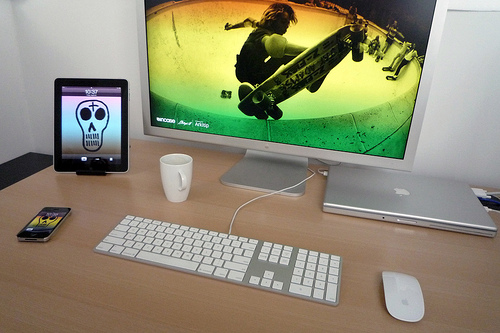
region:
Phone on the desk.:
[8, 201, 81, 254]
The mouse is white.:
[374, 248, 438, 330]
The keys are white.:
[93, 204, 350, 331]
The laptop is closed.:
[331, 166, 491, 244]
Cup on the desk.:
[154, 145, 204, 207]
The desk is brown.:
[33, 266, 209, 331]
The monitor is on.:
[124, 10, 433, 167]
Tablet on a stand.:
[45, 73, 135, 188]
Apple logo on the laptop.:
[381, 178, 428, 205]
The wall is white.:
[2, 3, 149, 71]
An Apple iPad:
[45, 70, 136, 193]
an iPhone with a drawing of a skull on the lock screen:
[15, 198, 71, 245]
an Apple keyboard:
[98, 198, 350, 310]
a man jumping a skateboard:
[148, 0, 414, 147]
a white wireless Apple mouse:
[375, 260, 432, 330]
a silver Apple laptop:
[318, 153, 497, 241]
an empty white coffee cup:
[150, 146, 197, 208]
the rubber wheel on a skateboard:
[247, 88, 272, 116]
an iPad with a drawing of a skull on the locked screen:
[45, 69, 135, 184]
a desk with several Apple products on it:
[2, 3, 490, 325]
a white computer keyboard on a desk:
[83, 207, 365, 317]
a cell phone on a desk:
[3, 174, 98, 261]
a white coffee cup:
[139, 138, 216, 216]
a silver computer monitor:
[123, 9, 452, 162]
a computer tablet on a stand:
[23, 38, 139, 188]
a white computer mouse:
[353, 263, 450, 332]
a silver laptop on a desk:
[297, 165, 496, 242]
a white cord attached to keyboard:
[218, 161, 326, 243]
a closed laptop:
[316, 172, 498, 237]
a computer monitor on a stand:
[120, 11, 462, 198]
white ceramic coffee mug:
[155, 145, 200, 202]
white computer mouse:
[382, 258, 429, 325]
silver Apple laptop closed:
[319, 153, 496, 240]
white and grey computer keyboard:
[90, 206, 355, 319]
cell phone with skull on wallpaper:
[16, 198, 71, 245]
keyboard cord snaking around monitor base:
[223, 167, 324, 242]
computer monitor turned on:
[135, 15, 429, 161]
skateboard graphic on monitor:
[218, 4, 363, 111]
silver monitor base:
[214, 141, 322, 208]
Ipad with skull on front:
[50, 68, 131, 183]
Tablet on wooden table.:
[55, 78, 133, 174]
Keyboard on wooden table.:
[91, 205, 345, 305]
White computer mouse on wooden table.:
[378, 267, 425, 320]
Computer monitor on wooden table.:
[131, 0, 456, 197]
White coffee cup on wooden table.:
[152, 152, 198, 205]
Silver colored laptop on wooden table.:
[320, 160, 498, 233]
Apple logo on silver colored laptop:
[386, 181, 414, 201]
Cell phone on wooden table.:
[12, 200, 72, 245]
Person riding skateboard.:
[221, 5, 368, 125]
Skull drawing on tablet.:
[75, 100, 110, 154]